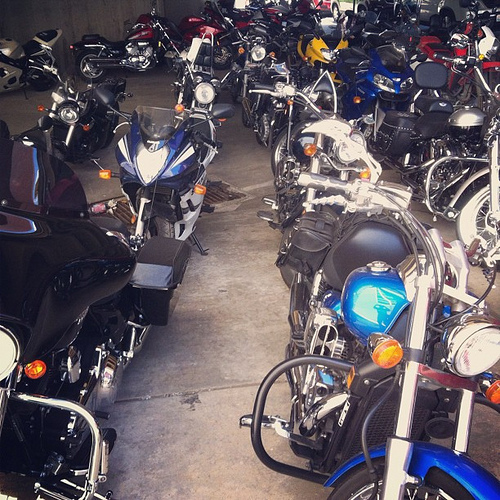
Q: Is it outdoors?
A: Yes, it is outdoors.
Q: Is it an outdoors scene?
A: Yes, it is outdoors.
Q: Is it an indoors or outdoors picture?
A: It is outdoors.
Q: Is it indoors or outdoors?
A: It is outdoors.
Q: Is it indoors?
A: No, it is outdoors.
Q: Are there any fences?
A: No, there are no fences.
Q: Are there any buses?
A: No, there are no buses.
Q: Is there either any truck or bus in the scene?
A: No, there are no buses or trucks.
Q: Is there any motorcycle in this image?
A: Yes, there are motorcycles.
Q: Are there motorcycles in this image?
A: Yes, there are motorcycles.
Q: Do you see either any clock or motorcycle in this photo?
A: Yes, there are motorcycles.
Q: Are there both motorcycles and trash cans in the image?
A: No, there are motorcycles but no trash cans.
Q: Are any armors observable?
A: No, there are no armors.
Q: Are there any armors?
A: No, there are no armors.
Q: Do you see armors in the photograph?
A: No, there are no armors.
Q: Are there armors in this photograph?
A: No, there are no armors.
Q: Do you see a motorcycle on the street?
A: Yes, there are motorcycles on the street.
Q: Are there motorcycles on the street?
A: Yes, there are motorcycles on the street.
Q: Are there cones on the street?
A: No, there are motorcycles on the street.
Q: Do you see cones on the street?
A: No, there are motorcycles on the street.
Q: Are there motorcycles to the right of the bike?
A: Yes, there are motorcycles to the right of the bike.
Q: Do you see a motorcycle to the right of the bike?
A: Yes, there are motorcycles to the right of the bike.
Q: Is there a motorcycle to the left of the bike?
A: No, the motorcycles are to the right of the bike.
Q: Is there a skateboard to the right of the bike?
A: No, there are motorcycles to the right of the bike.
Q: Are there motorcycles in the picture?
A: Yes, there is a motorcycle.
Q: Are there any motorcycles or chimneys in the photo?
A: Yes, there is a motorcycle.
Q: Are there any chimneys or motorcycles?
A: Yes, there is a motorcycle.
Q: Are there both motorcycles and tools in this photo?
A: No, there is a motorcycle but no tools.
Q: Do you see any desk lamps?
A: No, there are no desk lamps.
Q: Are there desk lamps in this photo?
A: No, there are no desk lamps.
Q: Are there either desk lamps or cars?
A: No, there are no desk lamps or cars.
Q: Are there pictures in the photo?
A: No, there are no pictures.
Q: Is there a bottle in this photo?
A: No, there are no bottles.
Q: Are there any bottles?
A: No, there are no bottles.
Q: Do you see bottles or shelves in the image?
A: No, there are no bottles or shelves.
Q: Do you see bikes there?
A: Yes, there is a bike.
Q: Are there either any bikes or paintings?
A: Yes, there is a bike.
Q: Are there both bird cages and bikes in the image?
A: No, there is a bike but no bird cages.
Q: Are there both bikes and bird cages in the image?
A: No, there is a bike but no bird cages.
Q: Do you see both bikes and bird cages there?
A: No, there is a bike but no bird cages.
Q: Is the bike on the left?
A: Yes, the bike is on the left of the image.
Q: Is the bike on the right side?
A: No, the bike is on the left of the image.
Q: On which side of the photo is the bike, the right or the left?
A: The bike is on the left of the image.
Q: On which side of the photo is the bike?
A: The bike is on the left of the image.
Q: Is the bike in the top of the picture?
A: Yes, the bike is in the top of the image.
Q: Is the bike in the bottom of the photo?
A: No, the bike is in the top of the image.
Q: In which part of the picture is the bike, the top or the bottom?
A: The bike is in the top of the image.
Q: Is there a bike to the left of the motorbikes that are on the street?
A: Yes, there is a bike to the left of the motorbikes.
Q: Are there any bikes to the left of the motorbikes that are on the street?
A: Yes, there is a bike to the left of the motorbikes.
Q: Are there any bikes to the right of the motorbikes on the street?
A: No, the bike is to the left of the motorbikes.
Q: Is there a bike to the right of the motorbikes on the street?
A: No, the bike is to the left of the motorbikes.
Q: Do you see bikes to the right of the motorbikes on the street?
A: No, the bike is to the left of the motorbikes.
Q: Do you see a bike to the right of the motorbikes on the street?
A: No, the bike is to the left of the motorbikes.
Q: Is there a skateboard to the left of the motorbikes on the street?
A: No, there is a bike to the left of the motorcycles.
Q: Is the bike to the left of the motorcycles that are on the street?
A: Yes, the bike is to the left of the motorcycles.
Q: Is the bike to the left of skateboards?
A: No, the bike is to the left of the motorcycles.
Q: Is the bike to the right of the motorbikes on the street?
A: No, the bike is to the left of the motorbikes.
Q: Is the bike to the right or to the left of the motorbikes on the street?
A: The bike is to the left of the motorbikes.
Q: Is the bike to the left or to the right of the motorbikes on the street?
A: The bike is to the left of the motorbikes.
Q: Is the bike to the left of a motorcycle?
A: Yes, the bike is to the left of a motorcycle.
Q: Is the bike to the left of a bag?
A: No, the bike is to the left of a motorcycle.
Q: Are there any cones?
A: No, there are no cones.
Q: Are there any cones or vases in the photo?
A: No, there are no cones or vases.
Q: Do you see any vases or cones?
A: No, there are no cones or vases.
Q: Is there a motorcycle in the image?
A: Yes, there is a motorcycle.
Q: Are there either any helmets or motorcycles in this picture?
A: Yes, there is a motorcycle.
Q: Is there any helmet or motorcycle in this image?
A: Yes, there is a motorcycle.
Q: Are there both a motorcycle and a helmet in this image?
A: No, there is a motorcycle but no helmets.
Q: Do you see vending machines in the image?
A: No, there are no vending machines.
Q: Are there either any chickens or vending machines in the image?
A: No, there are no vending machines or chickens.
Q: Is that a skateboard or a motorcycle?
A: That is a motorcycle.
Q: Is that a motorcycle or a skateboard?
A: That is a motorcycle.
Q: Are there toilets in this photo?
A: No, there are no toilets.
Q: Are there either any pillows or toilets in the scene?
A: No, there are no toilets or pillows.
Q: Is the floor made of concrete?
A: Yes, the floor is made of concrete.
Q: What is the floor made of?
A: The floor is made of cement.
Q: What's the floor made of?
A: The floor is made of concrete.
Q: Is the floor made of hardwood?
A: No, the floor is made of cement.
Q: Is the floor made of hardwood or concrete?
A: The floor is made of concrete.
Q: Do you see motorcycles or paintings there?
A: Yes, there is a motorcycle.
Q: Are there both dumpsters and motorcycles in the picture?
A: No, there is a motorcycle but no dumpsters.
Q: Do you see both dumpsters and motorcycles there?
A: No, there is a motorcycle but no dumpsters.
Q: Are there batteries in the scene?
A: No, there are no batteries.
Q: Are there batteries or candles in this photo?
A: No, there are no batteries or candles.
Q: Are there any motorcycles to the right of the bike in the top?
A: Yes, there is a motorcycle to the right of the bike.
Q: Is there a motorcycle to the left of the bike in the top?
A: No, the motorcycle is to the right of the bike.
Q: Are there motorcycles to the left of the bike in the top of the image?
A: No, the motorcycle is to the right of the bike.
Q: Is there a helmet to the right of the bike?
A: No, there is a motorcycle to the right of the bike.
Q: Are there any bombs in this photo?
A: No, there are no bombs.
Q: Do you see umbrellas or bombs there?
A: No, there are no bombs or umbrellas.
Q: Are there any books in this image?
A: No, there are no books.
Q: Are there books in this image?
A: No, there are no books.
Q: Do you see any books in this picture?
A: No, there are no books.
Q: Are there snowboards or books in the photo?
A: No, there are no books or snowboards.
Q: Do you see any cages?
A: No, there are no cages.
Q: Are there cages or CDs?
A: No, there are no cages or cds.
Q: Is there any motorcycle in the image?
A: Yes, there is a motorcycle.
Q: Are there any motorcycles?
A: Yes, there is a motorcycle.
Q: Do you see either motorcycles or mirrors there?
A: Yes, there is a motorcycle.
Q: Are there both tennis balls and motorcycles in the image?
A: No, there is a motorcycle but no tennis balls.